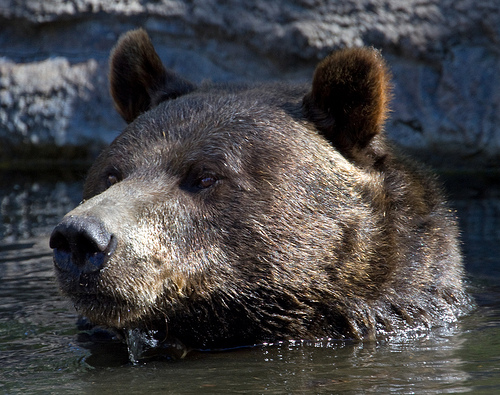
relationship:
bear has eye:
[42, 26, 480, 361] [179, 170, 219, 192]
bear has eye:
[42, 26, 480, 361] [96, 165, 123, 185]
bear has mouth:
[42, 26, 480, 361] [83, 285, 182, 337]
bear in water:
[42, 26, 480, 361] [1, 161, 499, 393]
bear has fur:
[42, 26, 480, 361] [83, 270, 473, 343]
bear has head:
[42, 26, 480, 361] [47, 25, 391, 352]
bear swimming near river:
[43, 26, 477, 354] [1, 159, 499, 394]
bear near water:
[42, 26, 480, 361] [1, 161, 499, 393]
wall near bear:
[0, 0, 498, 180] [42, 26, 480, 361]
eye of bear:
[97, 170, 125, 188] [42, 26, 480, 361]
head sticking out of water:
[47, 25, 391, 352] [1, 352, 497, 392]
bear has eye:
[42, 26, 480, 361] [192, 172, 220, 191]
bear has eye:
[42, 26, 480, 361] [104, 172, 120, 188]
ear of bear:
[299, 44, 396, 160] [42, 26, 480, 361]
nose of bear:
[55, 211, 145, 263] [75, 57, 487, 348]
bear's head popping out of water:
[50, 25, 475, 362] [1, 161, 499, 393]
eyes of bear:
[97, 166, 224, 186] [45, 52, 334, 379]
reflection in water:
[298, 336, 470, 392] [1, 352, 497, 392]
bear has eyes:
[42, 26, 480, 361] [96, 163, 237, 199]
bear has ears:
[42, 26, 480, 361] [302, 39, 388, 151]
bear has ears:
[42, 26, 480, 361] [106, 28, 197, 126]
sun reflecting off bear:
[118, 179, 186, 274] [85, 112, 435, 338]